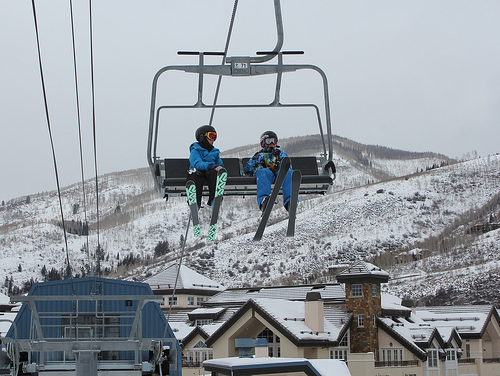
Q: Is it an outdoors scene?
A: Yes, it is outdoors.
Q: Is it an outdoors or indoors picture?
A: It is outdoors.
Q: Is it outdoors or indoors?
A: It is outdoors.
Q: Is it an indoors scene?
A: No, it is outdoors.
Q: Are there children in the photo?
A: Yes, there are children.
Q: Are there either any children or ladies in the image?
A: Yes, there are children.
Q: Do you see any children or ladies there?
A: Yes, there are children.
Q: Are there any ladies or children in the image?
A: Yes, there are children.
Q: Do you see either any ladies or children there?
A: Yes, there are children.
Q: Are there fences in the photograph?
A: No, there are no fences.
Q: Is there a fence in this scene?
A: No, there are no fences.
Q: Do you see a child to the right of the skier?
A: Yes, there are children to the right of the skier.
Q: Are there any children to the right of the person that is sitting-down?
A: Yes, there are children to the right of the skier.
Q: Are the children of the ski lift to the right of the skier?
A: Yes, the children are to the right of the skier.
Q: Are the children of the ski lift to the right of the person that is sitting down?
A: Yes, the children are to the right of the skier.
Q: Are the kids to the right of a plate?
A: No, the kids are to the right of the skier.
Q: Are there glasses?
A: No, there are no glasses.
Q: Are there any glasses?
A: No, there are no glasses.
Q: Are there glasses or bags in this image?
A: No, there are no glasses or bags.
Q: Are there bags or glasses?
A: No, there are no glasses or bags.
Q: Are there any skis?
A: Yes, there are skis.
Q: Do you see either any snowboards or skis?
A: Yes, there are skis.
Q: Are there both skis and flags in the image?
A: No, there are skis but no flags.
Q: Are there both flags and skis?
A: No, there are skis but no flags.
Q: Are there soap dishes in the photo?
A: No, there are no soap dishes.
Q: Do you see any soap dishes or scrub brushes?
A: No, there are no soap dishes or scrub brushes.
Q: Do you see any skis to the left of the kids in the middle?
A: Yes, there are skis to the left of the kids.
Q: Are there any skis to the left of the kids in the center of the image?
A: Yes, there are skis to the left of the kids.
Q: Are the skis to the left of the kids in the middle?
A: Yes, the skis are to the left of the kids.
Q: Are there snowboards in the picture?
A: No, there are no snowboards.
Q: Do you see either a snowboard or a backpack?
A: No, there are no snowboards or backpacks.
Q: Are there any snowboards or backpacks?
A: No, there are no snowboards or backpacks.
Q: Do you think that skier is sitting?
A: Yes, the skier is sitting.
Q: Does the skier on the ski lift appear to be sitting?
A: Yes, the skier is sitting.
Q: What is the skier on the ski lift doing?
A: The skier is sitting.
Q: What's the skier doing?
A: The skier is sitting.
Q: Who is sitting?
A: The skier is sitting.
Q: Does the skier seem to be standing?
A: No, the skier is sitting.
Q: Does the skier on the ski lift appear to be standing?
A: No, the skier is sitting.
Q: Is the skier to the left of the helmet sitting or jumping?
A: The skier is sitting.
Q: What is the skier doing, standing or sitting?
A: The skier is sitting.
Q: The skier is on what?
A: The skier is on the ski lift.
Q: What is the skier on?
A: The skier is on the ski lift.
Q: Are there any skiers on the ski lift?
A: Yes, there is a skier on the ski lift.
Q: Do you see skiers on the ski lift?
A: Yes, there is a skier on the ski lift.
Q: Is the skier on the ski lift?
A: Yes, the skier is on the ski lift.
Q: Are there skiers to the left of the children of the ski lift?
A: Yes, there is a skier to the left of the children.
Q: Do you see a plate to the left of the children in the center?
A: No, there is a skier to the left of the children.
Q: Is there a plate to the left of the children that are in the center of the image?
A: No, there is a skier to the left of the children.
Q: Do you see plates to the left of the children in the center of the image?
A: No, there is a skier to the left of the children.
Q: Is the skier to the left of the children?
A: Yes, the skier is to the left of the children.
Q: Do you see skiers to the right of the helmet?
A: No, the skier is to the left of the helmet.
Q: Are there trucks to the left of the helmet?
A: No, there is a skier to the left of the helmet.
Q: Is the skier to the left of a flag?
A: No, the skier is to the left of the helmet.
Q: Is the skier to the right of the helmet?
A: No, the skier is to the left of the helmet.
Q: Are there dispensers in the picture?
A: No, there are no dispensers.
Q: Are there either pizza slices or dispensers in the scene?
A: No, there are no dispensers or pizza slices.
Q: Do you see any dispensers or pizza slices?
A: No, there are no dispensers or pizza slices.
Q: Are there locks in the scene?
A: No, there are no locks.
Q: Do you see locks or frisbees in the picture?
A: No, there are no locks or frisbees.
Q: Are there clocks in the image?
A: No, there are no clocks.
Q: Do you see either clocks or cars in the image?
A: No, there are no clocks or cars.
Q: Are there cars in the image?
A: No, there are no cars.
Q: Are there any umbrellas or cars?
A: No, there are no cars or umbrellas.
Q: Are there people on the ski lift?
A: Yes, there are people on the ski lift.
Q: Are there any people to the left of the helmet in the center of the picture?
A: Yes, there are people to the left of the helmet.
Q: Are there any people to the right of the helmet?
A: No, the people are to the left of the helmet.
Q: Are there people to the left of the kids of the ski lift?
A: Yes, there are people to the left of the kids.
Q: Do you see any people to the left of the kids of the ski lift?
A: Yes, there are people to the left of the kids.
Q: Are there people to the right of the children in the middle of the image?
A: No, the people are to the left of the kids.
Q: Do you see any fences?
A: No, there are no fences.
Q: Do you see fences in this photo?
A: No, there are no fences.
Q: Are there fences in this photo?
A: No, there are no fences.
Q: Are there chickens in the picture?
A: No, there are no chickens.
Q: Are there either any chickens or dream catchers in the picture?
A: No, there are no chickens or dream catchers.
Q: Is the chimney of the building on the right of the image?
A: Yes, the chimney is on the right of the image.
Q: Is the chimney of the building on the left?
A: No, the chimney is on the right of the image.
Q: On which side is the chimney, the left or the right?
A: The chimney is on the right of the image.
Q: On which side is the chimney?
A: The chimney is on the right of the image.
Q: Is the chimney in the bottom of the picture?
A: Yes, the chimney is in the bottom of the image.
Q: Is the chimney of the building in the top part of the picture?
A: No, the chimney is in the bottom of the image.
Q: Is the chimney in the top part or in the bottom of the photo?
A: The chimney is in the bottom of the image.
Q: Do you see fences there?
A: No, there are no fences.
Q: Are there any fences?
A: No, there are no fences.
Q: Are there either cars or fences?
A: No, there are no fences or cars.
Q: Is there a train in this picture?
A: No, there are no trains.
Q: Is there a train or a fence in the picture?
A: No, there are no trains or fences.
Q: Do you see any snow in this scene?
A: Yes, there is snow.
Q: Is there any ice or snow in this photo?
A: Yes, there is snow.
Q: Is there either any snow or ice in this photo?
A: Yes, there is snow.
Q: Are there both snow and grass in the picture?
A: No, there is snow but no grass.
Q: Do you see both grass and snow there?
A: No, there is snow but no grass.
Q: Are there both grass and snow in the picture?
A: No, there is snow but no grass.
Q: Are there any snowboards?
A: No, there are no snowboards.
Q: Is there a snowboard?
A: No, there are no snowboards.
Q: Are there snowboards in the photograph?
A: No, there are no snowboards.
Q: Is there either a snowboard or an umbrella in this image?
A: No, there are no snowboards or umbrellas.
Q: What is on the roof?
A: The snow is on the roof.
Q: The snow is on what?
A: The snow is on the roof.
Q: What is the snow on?
A: The snow is on the roof.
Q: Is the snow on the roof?
A: Yes, the snow is on the roof.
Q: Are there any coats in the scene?
A: Yes, there is a coat.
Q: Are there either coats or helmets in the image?
A: Yes, there is a coat.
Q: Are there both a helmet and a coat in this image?
A: Yes, there are both a coat and a helmet.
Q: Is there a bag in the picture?
A: No, there are no bags.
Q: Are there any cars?
A: No, there are no cars.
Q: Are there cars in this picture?
A: No, there are no cars.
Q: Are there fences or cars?
A: No, there are no cars or fences.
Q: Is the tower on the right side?
A: Yes, the tower is on the right of the image.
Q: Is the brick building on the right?
A: Yes, the tower is on the right of the image.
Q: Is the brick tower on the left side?
A: No, the tower is on the right of the image.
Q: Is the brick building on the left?
A: No, the tower is on the right of the image.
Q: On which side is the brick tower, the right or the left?
A: The tower is on the right of the image.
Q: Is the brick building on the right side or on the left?
A: The tower is on the right of the image.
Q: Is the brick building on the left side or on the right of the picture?
A: The tower is on the right of the image.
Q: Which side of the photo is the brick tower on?
A: The tower is on the right of the image.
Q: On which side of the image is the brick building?
A: The tower is on the right of the image.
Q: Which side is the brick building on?
A: The tower is on the right of the image.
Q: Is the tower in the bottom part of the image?
A: Yes, the tower is in the bottom of the image.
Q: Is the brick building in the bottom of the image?
A: Yes, the tower is in the bottom of the image.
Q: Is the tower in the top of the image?
A: No, the tower is in the bottom of the image.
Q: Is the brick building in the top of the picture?
A: No, the tower is in the bottom of the image.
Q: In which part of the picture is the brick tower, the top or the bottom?
A: The tower is in the bottom of the image.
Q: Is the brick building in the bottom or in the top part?
A: The tower is in the bottom of the image.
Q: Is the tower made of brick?
A: Yes, the tower is made of brick.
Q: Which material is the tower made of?
A: The tower is made of brick.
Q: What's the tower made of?
A: The tower is made of brick.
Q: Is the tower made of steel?
A: No, the tower is made of brick.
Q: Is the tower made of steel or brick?
A: The tower is made of brick.